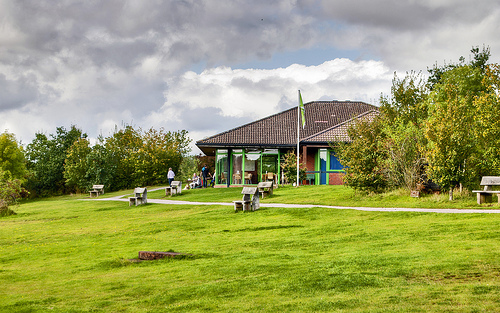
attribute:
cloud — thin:
[1, 0, 498, 158]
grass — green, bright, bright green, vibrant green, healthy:
[1, 183, 498, 310]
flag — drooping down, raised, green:
[300, 96, 306, 130]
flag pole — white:
[298, 90, 301, 188]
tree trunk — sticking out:
[447, 185, 454, 202]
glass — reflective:
[246, 152, 261, 185]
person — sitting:
[196, 177, 202, 189]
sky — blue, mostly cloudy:
[1, 3, 498, 154]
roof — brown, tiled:
[196, 100, 385, 156]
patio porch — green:
[217, 151, 282, 186]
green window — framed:
[214, 151, 281, 183]